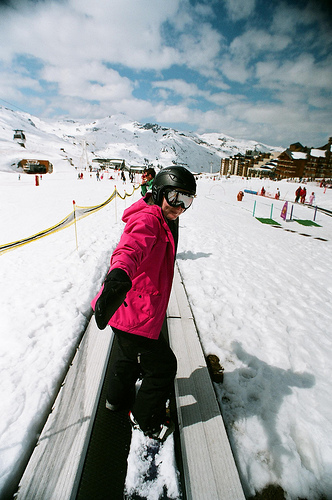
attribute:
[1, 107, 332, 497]
snow — white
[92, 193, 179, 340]
jacket — ping, pink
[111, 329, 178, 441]
pants — black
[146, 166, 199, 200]
helmet — black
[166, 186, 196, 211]
goggles — black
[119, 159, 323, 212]
people — not bananas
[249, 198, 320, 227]
posts — not bananas, green, blue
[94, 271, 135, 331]
hand — black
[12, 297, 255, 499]
wood — white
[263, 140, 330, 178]
buildings — not bananas, brown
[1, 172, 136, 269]
yellow tape — not bananas